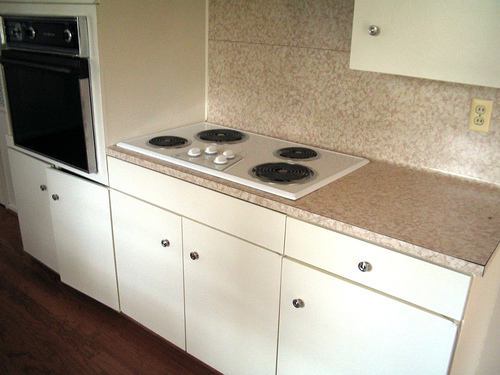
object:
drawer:
[284, 217, 474, 326]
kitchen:
[2, 2, 500, 372]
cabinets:
[181, 212, 281, 372]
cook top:
[118, 120, 368, 202]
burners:
[149, 135, 188, 146]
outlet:
[469, 98, 492, 132]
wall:
[103, 3, 203, 128]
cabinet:
[347, 0, 499, 89]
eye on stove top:
[295, 150, 302, 154]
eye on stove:
[278, 169, 288, 173]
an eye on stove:
[218, 133, 224, 136]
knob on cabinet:
[38, 183, 48, 189]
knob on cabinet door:
[51, 193, 61, 201]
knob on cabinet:
[161, 239, 170, 247]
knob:
[292, 300, 305, 308]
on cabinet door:
[357, 261, 371, 271]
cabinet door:
[182, 217, 280, 373]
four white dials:
[188, 145, 235, 164]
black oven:
[1, 15, 91, 173]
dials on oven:
[213, 155, 228, 164]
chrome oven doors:
[3, 54, 90, 174]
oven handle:
[0, 57, 76, 76]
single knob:
[368, 25, 379, 36]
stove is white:
[243, 144, 272, 164]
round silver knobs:
[189, 251, 199, 260]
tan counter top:
[108, 119, 496, 276]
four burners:
[147, 128, 319, 185]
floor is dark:
[0, 301, 94, 375]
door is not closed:
[47, 164, 120, 313]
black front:
[0, 14, 88, 176]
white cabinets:
[279, 254, 459, 375]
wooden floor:
[1, 207, 218, 375]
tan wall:
[211, 3, 343, 128]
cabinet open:
[46, 164, 120, 317]